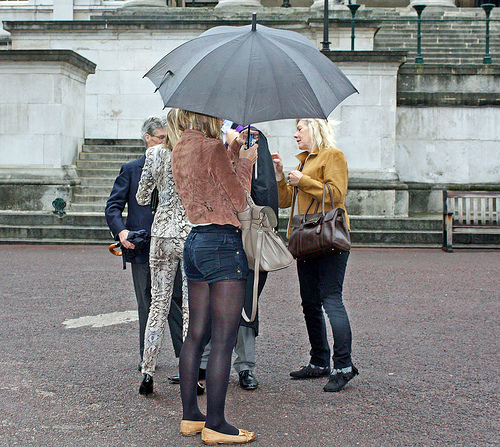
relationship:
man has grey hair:
[104, 117, 183, 371] [141, 116, 167, 148]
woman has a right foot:
[271, 119, 359, 394] [290, 365, 332, 379]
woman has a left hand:
[271, 119, 359, 394] [288, 170, 304, 187]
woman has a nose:
[271, 119, 359, 394] [294, 131, 299, 137]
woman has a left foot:
[271, 119, 359, 394] [323, 367, 357, 392]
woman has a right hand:
[271, 119, 359, 394] [271, 153, 284, 180]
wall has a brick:
[0, 49, 98, 184] [33, 104, 67, 135]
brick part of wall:
[33, 104, 67, 135] [0, 49, 98, 184]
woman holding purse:
[271, 119, 359, 394] [287, 182, 350, 259]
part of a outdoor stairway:
[73, 114, 120, 294] [0, 137, 499, 248]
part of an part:
[23, 318, 79, 428] [144, 13, 359, 128]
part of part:
[124, 49, 324, 135] [144, 13, 359, 128]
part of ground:
[23, 318, 79, 428] [1, 241, 498, 446]